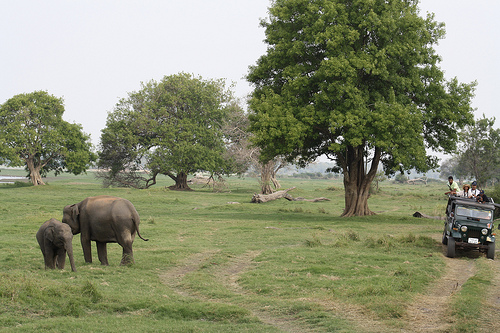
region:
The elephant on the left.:
[37, 208, 76, 270]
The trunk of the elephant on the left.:
[61, 238, 83, 271]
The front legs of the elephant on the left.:
[38, 247, 68, 268]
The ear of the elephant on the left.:
[45, 227, 57, 243]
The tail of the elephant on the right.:
[130, 212, 155, 249]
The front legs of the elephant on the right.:
[80, 235, 110, 260]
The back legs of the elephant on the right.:
[121, 237, 131, 264]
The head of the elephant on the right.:
[55, 195, 84, 235]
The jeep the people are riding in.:
[435, 187, 497, 266]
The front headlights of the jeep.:
[459, 220, 491, 236]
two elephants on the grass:
[26, 191, 193, 288]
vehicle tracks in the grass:
[174, 252, 492, 328]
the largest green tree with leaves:
[283, 10, 423, 220]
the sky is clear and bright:
[27, 17, 157, 58]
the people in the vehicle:
[436, 173, 499, 255]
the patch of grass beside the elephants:
[16, 278, 140, 320]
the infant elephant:
[22, 218, 82, 282]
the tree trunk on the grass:
[247, 185, 332, 205]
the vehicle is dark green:
[426, 193, 495, 262]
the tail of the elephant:
[126, 217, 158, 245]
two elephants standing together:
[35, 195, 149, 272]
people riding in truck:
[443, 175, 495, 260]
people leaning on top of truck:
[444, 175, 490, 205]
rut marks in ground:
[157, 247, 498, 332]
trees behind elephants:
[0, 0, 499, 219]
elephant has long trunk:
[62, 236, 77, 272]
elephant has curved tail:
[130, 216, 149, 241]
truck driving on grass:
[0, 168, 498, 332]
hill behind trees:
[0, 149, 477, 184]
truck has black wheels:
[440, 225, 496, 258]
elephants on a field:
[32, 200, 157, 265]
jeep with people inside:
[437, 176, 499, 261]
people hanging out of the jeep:
[442, 171, 489, 203]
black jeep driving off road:
[440, 195, 499, 257]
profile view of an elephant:
[63, 197, 148, 268]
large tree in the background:
[254, 0, 466, 218]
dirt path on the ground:
[162, 235, 499, 330]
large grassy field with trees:
[1, 187, 496, 329]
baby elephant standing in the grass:
[39, 217, 76, 279]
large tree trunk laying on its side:
[249, 188, 296, 202]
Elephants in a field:
[27, 192, 149, 279]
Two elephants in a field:
[29, 188, 153, 270]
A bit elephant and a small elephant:
[25, 194, 145, 278]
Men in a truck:
[441, 173, 499, 258]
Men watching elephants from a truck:
[17, 158, 497, 272]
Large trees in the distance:
[6, 72, 246, 203]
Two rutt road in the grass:
[166, 235, 355, 332]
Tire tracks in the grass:
[165, 237, 367, 331]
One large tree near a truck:
[255, 6, 481, 223]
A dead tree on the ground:
[240, 182, 336, 205]